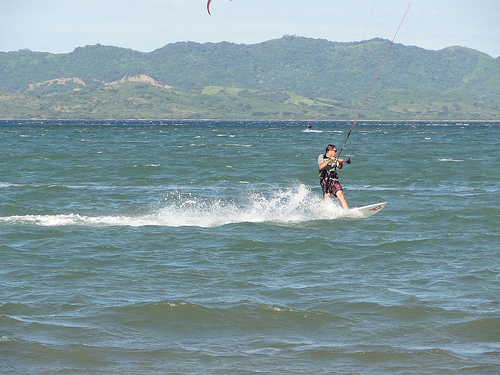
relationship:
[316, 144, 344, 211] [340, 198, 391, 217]
man on skies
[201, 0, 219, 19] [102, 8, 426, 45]
kite in air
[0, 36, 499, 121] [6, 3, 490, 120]
hills in background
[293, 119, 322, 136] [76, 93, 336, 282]
person in ocean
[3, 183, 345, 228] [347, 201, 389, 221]
white water behind board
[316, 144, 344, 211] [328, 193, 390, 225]
man on surf board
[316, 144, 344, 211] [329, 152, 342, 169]
man holding handle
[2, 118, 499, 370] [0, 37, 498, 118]
water by shore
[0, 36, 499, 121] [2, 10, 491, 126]
hills in background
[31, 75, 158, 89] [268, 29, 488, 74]
hills in mountains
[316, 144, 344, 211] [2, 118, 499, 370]
man in water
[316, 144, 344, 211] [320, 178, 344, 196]
man with shorts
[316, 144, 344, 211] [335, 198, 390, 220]
man on surfboard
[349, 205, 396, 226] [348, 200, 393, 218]
logo on board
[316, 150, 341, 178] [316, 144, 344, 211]
shirt on man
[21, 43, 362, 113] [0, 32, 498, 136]
trees on hill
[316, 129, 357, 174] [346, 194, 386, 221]
man creating wake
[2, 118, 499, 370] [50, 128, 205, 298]
water in water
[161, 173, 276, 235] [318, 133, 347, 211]
spray by wind surfer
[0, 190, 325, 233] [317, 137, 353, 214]
wake left behind wind surfer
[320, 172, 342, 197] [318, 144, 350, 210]
shorts on wind surfer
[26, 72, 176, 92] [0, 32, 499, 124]
stone on land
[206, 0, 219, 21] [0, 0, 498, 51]
kite in sky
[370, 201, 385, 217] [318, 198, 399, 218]
logo on a board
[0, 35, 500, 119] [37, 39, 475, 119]
trees growing on hills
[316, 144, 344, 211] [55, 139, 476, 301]
man windsurfing on ocean